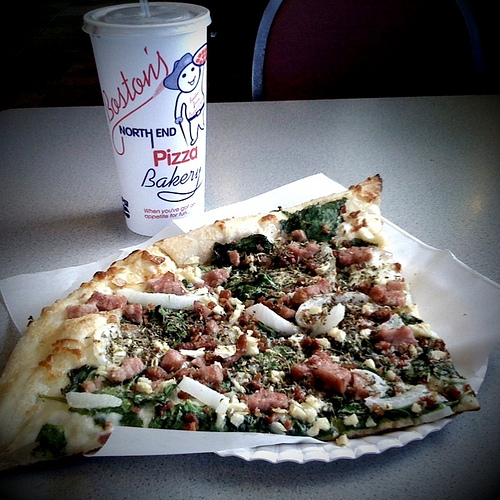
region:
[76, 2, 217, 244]
a white soda cup with Boston's North End Pizza logo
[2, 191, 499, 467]
two slices of pizza with many toppings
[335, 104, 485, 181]
a white shiny table the food is sitting on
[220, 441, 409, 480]
the edge of a white paper plate that holds the pizza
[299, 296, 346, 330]
a mushroom on the slice of pizza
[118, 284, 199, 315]
a piece of onion on the pizza slice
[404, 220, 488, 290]
the edge of a white napkin the pizza is on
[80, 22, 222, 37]
the plastic lid of the soda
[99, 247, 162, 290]
pizza crust with cheese baked in it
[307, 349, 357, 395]
a chunk of meat on the pizza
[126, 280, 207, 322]
slice of onion on the pizza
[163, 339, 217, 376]
chunks of pepperoni on the pizza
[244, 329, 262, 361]
feta cheese sprinkled on the pizza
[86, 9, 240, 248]
a cup of soda on the tabl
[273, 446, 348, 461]
a serrated edge on the paper plate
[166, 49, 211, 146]
the drawing of a man on the cup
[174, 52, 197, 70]
a hat on the man's head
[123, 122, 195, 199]
red and blue writing on the cup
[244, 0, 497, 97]
a red cushioned chair next to the table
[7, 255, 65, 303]
a piece of white wax paper under the pizza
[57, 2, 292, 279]
Drink on the table.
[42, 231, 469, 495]
Pizza on the table.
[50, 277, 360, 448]
Meat on the pizza.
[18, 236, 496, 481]
Plate under the pizza.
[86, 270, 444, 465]
Vegetables on the pizza.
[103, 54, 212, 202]
Writing on the cup.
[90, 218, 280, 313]
Crust of the pizza.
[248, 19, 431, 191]
Chair behind the table.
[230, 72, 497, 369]
Table with food on it.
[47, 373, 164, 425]
Onion on the pizza.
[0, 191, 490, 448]
a tasty portion of pizza.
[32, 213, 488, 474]
a delicious portion of pizza.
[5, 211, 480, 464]
a flavorful portion of pizza.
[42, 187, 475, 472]
a nice sized portion of pizza.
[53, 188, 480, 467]
a well seasoned portion of pizza.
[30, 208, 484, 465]
pizza portion with multiple toppings.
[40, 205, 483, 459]
pizza portions covered with delicious toppings.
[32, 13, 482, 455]
delicious pizza with a nice beverage.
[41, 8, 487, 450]
tasty pizza portions with sweet beverage.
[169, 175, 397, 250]
tasty pizza crust with great flavorings.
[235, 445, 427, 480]
fluted white paper plate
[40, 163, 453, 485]
piece of delicious meat and vegetable pizza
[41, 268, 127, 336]
toasty pizza crust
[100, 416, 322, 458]
crisp piece of white paper under the pizza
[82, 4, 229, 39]
clear plastic beverage lid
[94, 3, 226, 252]
soft drink container with a straw and a lid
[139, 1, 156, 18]
white and blue striped plastic straw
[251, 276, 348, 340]
chunks of onions on the pizza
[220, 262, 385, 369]
zesty herbs topping the pizza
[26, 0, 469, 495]
meal of pizza and a beverage